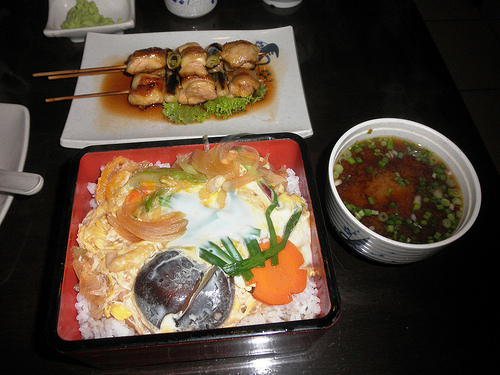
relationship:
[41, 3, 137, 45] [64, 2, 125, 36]
dish full of wasabi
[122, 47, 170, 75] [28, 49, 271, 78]
meat served on a stick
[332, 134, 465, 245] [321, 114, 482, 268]
miso soup inside bowl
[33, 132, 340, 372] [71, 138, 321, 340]
dish full of food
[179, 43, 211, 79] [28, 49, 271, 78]
fish served on a stick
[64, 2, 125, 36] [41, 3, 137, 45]
wasabi served on dish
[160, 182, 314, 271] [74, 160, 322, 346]
liquid served over rice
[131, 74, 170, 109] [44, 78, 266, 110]
food served on skewer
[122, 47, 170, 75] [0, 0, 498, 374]
meat on top of table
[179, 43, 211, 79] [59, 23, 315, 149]
fish on top of plate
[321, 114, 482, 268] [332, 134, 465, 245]
bowl full of miso soup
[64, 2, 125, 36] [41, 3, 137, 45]
wasabi served in dish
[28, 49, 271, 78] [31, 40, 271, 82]
stick used for skewering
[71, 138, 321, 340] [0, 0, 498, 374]
food served on a table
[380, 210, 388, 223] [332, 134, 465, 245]
onion served in miso soup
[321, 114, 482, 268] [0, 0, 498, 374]
bowl on top of table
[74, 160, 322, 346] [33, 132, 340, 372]
rice served in a dish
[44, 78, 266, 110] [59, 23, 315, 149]
skewer on top of plate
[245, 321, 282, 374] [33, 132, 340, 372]
light reflecting off dish